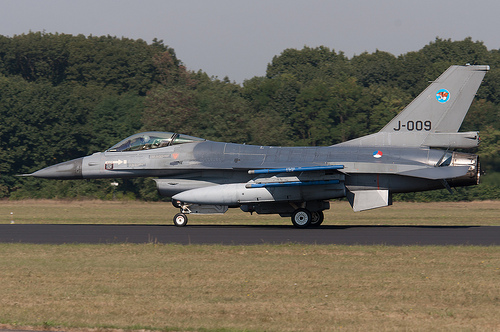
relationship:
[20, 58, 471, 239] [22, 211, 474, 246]
jet sits on runway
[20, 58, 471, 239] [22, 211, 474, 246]
jet on runway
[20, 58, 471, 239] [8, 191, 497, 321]
jet on ground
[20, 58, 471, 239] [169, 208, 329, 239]
jet on wheels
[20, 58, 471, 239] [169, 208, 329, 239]
jet has wheels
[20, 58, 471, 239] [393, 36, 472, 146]
jet has tail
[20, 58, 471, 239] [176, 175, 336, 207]
jet has missile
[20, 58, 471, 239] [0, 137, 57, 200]
jet has nose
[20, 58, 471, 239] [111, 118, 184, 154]
jet has cockpit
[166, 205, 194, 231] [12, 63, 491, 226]
wheel of jet